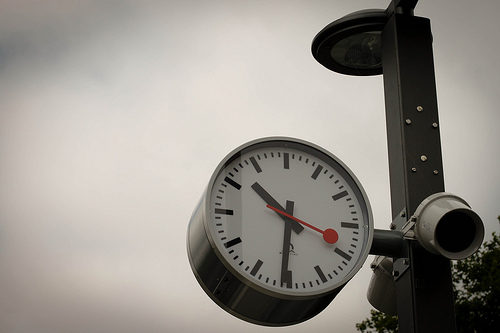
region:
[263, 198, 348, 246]
Red hand on a clock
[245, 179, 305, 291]
Black hand on a clock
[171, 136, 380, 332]
A round clock with a white face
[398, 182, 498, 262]
A grey security camera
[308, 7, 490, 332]
A pole that a clock is attached to.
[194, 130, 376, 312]
A circle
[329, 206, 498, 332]
A tree behind a pole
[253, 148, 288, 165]
Minute increments on a clock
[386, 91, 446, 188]
Screws on a black pole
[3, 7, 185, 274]
A sky that appears white and grey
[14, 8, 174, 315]
overcast sky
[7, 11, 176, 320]
stormy afternoon sky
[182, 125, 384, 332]
round outdoor clock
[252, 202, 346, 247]
red second hand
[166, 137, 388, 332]
black, white, and red clock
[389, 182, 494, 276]
closed circut security camera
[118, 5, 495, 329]
light post with light, clock, and camera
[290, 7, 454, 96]
bulb on a light post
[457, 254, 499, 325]
tree with dark leaves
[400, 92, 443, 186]
six shiney silver bolts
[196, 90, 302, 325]
a clock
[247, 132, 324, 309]
a clock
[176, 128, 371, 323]
black and white clock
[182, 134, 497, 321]
clock hanging off a pole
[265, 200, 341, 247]
red hand for seconds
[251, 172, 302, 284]
two black clock hands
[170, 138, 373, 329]
round clock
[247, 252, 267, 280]
thick black line on the clock face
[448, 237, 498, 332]
small, dark tree top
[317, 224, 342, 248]
red circle on the end of the seconds hand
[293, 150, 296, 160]
small white line to signify the minutes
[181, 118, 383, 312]
clock indicating it's 10:30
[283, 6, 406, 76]
light on top of pole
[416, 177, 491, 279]
light on side of pole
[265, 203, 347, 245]
red hand in clock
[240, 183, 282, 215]
short hand on clock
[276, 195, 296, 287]
Long hand on clock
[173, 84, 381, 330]
clock on side of pole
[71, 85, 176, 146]
Clear cloudy grey skies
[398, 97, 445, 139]
first set of screws on pole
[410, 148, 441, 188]
second set of screws on pole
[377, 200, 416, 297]
third set of screws on pole